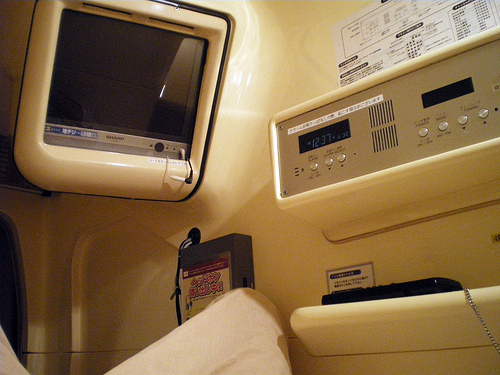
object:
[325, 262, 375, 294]
cover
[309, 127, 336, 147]
lights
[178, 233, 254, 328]
box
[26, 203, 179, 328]
wall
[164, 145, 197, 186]
cords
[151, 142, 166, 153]
sensor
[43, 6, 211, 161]
display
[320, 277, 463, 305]
black remote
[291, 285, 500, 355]
counter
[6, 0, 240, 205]
machine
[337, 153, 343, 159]
button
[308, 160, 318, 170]
button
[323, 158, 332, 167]
button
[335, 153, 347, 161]
button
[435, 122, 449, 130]
button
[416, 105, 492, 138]
four buttons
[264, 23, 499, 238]
controls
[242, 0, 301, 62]
wall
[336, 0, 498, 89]
diagram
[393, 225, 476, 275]
wall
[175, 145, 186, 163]
button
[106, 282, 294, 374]
pillow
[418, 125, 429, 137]
button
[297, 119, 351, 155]
clock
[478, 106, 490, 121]
button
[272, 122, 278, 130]
screw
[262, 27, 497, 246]
box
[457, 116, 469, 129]
button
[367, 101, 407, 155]
speaker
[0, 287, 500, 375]
bed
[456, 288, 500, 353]
cord